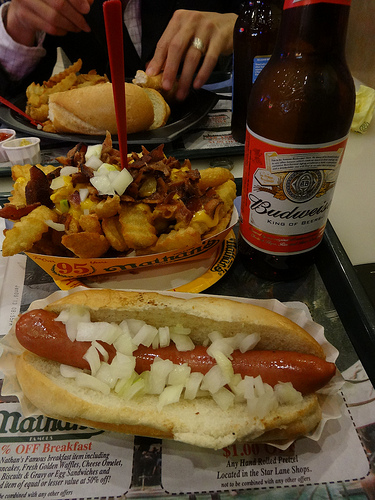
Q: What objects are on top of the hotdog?
A: Onions.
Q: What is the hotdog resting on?
A: Bun.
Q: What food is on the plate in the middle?
A: Fries.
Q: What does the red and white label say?
A: Budweiser.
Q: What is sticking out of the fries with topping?
A: Red utensil.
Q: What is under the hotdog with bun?
A: Newspaper.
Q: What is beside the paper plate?
A: Bottle of beer.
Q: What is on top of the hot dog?
A: Onions.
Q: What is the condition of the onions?
A: Diced.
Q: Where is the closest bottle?
A: Right of the fries.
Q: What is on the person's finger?
A: Ring.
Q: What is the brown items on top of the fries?
A: Bacon.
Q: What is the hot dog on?
A: A bun.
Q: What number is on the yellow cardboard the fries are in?
A: 95.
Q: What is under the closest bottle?
A: Tray.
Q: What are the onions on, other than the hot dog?
A: Fries.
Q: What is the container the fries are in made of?
A: Cardboard.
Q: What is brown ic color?
A: The bottle of beer.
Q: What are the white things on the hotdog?
A: They are onions.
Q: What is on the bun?
A: A hotdog.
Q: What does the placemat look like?
A: The placemat looks like coupons.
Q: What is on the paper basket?
A: Brown french fries.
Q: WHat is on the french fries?
A: There are onions on the french fries.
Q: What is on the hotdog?
A: There are onions on the hot dog.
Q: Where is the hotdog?
A: The hot dog is on a bun.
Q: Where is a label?
A: On a bottle.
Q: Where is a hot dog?
A: In a bun.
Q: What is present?
A: Food.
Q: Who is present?
A: A person.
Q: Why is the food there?
A: To be eaten.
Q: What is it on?
A: A table.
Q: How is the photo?
A: Clear.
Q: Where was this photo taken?
A: At a restaurant.